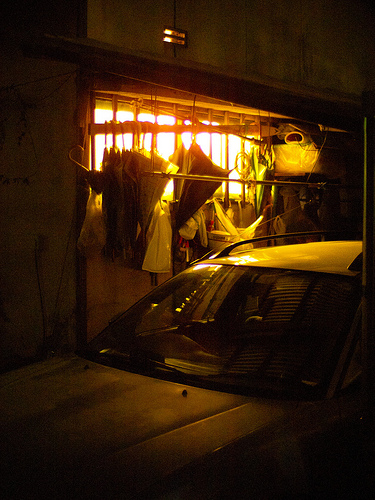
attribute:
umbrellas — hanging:
[80, 141, 220, 222]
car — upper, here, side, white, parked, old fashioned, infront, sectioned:
[106, 224, 357, 433]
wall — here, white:
[27, 59, 72, 138]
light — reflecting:
[126, 107, 291, 281]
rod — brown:
[123, 75, 254, 137]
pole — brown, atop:
[93, 119, 318, 149]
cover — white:
[184, 205, 322, 282]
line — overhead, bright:
[122, 53, 250, 122]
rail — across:
[102, 150, 365, 251]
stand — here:
[88, 125, 172, 215]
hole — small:
[44, 353, 109, 382]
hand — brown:
[115, 115, 143, 141]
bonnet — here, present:
[219, 232, 371, 356]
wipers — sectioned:
[201, 324, 304, 386]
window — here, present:
[133, 286, 217, 362]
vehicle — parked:
[73, 191, 373, 495]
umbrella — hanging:
[135, 147, 205, 259]